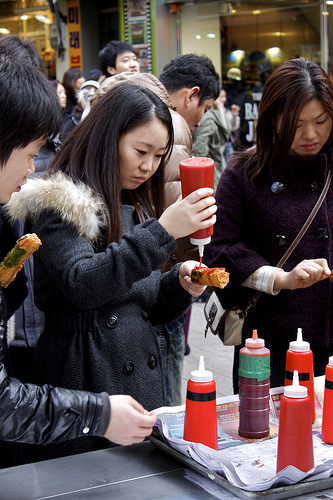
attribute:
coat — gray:
[5, 168, 193, 396]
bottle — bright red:
[243, 375, 268, 432]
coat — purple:
[64, 249, 155, 373]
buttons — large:
[79, 422, 95, 440]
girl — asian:
[275, 91, 330, 147]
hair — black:
[252, 132, 277, 168]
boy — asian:
[171, 64, 206, 105]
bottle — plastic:
[226, 339, 270, 427]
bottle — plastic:
[188, 369, 217, 435]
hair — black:
[0, 38, 65, 163]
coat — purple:
[204, 135, 331, 381]